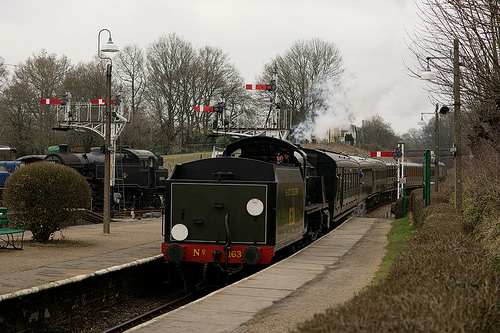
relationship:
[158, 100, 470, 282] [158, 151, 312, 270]
train has car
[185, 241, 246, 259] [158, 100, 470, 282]
writing on train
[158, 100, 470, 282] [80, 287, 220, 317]
train travels on track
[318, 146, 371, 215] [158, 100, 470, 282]
car part of train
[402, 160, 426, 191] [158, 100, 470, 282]
passenger car part of train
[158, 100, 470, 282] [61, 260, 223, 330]
train on tracks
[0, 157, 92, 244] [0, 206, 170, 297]
bush on sidewalk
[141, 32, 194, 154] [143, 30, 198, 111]
tree has branches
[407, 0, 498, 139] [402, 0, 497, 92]
tree has branches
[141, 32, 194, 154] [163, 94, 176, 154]
tree has trunk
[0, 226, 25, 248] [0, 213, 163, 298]
bench on sidewalk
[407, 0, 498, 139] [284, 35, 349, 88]
tree has branches